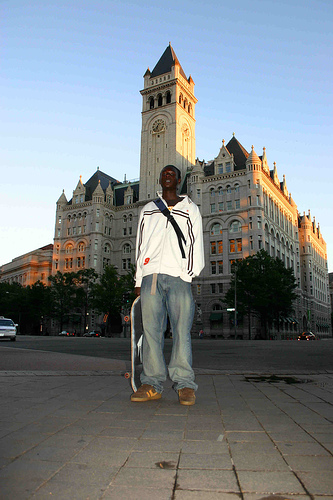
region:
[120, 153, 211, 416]
man standing next to skateboard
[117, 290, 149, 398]
skateboard standing up next to man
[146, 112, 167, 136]
clock on a tower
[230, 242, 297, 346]
green tree by building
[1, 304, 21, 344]
white car in the street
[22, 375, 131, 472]
paved ground of a sidewalk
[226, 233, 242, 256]
window of a building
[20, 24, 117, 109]
blue sky in the distance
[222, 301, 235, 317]
street sign on a pole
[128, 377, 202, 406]
man's brown and orange sneakers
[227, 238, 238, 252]
a window of a building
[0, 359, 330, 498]
part of a sidewalk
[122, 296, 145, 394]
part of a black skateboard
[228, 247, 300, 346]
a large green tree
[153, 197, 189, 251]
a black strap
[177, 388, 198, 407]
a boy's brown shoe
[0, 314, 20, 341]
part of a white car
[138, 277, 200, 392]
a boy's blue jean pants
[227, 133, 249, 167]
part of a roof of a building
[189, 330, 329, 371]
part of a paved roadway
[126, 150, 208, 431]
Man standing on the sidewalk.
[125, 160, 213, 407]
Man standing on the sidewalk with a skateboard.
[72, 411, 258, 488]
Sidewalk made up of bricks.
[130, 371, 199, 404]
Man wearing brown sneakers.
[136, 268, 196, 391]
Man wearing blue jeans.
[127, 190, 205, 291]
Man wearing a black and white jacket.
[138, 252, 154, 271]
Red number nine on the jacket.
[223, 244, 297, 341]
Large green tree across the street.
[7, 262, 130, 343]
Many trees line the sidewalk.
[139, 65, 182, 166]
Large spire with a clock.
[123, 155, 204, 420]
a man standing in front of a large building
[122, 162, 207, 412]
a man holding a skateboard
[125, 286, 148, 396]
a skateboard in a man's hand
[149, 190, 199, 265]
a strap across a jacket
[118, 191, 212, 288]
a black and white jacket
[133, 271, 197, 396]
a pair of blue jeans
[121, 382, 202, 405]
brown tennis shoes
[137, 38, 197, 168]
a clock tower on a building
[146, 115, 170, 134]
the face of a clock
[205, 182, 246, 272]
windows on a building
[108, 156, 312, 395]
a man standing outside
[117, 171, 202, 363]
a man standing on a sidewalk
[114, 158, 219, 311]
a man wearing a jacket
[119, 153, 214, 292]
a man wearing a white jacket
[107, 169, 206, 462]
a man wearing pants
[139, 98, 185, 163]
a clock on a building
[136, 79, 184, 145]
a clock on a large building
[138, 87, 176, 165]
a building with a clock